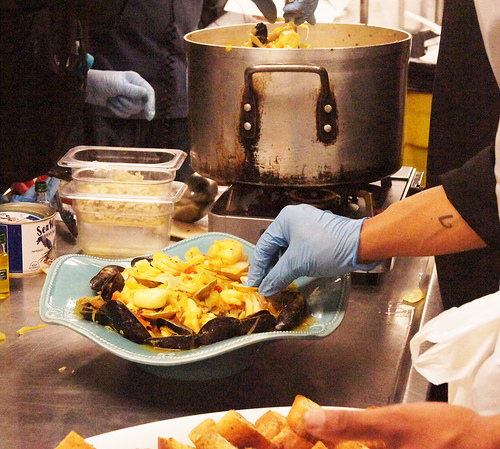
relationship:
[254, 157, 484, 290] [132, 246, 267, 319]
worker with food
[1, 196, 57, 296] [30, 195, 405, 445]
ingredients on counter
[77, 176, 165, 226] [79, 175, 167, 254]
food in dish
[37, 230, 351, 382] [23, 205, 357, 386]
dish served in bowl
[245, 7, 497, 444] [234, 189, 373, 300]
worker wears gloves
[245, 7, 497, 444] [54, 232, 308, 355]
worker preparing food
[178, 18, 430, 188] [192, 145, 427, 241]
pot sits on stove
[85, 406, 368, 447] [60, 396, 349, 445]
plate containing bread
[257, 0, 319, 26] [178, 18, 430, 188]
hand stirs pot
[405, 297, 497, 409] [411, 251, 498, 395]
apron tied around waist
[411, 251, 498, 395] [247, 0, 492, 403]
waist of worker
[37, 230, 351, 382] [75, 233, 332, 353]
dish containing food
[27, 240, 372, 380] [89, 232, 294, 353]
dish containing food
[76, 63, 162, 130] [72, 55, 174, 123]
hand with gloves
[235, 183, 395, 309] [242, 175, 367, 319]
hand with gloves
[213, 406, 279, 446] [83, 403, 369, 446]
bread on plate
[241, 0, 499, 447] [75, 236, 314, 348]
man grabbing food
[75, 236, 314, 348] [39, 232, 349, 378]
food in bowl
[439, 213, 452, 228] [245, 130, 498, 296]
tattoo on arm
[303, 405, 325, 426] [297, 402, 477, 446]
fingernail on thumb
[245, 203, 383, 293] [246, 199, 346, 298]
glove on hand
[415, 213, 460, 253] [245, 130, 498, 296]
vein on arm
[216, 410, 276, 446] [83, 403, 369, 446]
potato wedge on plate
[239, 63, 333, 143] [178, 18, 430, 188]
handle on pot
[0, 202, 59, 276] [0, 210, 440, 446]
can on table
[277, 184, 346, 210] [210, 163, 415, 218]
burner on top of stove top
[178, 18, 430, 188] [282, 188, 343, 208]
pot on burner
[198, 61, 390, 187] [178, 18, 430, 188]
rust on pot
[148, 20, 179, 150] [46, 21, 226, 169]
wire hanging from person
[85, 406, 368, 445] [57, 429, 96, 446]
plate with food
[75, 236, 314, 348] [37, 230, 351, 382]
food on dish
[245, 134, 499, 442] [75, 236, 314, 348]
person arranding food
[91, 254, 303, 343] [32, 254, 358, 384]
food in bowl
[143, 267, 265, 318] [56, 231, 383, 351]
chips in bowl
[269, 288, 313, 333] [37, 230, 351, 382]
mussel on dish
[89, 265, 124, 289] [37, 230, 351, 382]
mussel on dish